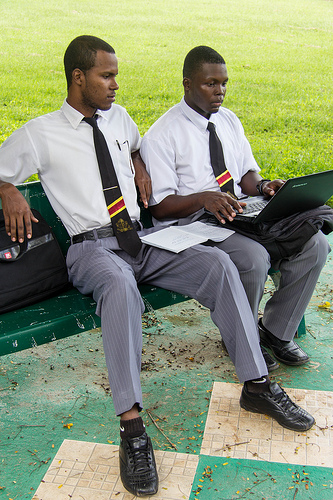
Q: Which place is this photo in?
A: It is at the field.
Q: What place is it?
A: It is a field.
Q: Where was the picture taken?
A: It was taken at the field.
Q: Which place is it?
A: It is a field.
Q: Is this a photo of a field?
A: Yes, it is showing a field.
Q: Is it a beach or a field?
A: It is a field.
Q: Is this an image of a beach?
A: No, the picture is showing a field.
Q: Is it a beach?
A: No, it is a field.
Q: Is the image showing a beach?
A: No, the picture is showing a field.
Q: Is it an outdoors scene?
A: Yes, it is outdoors.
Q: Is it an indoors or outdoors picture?
A: It is outdoors.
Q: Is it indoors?
A: No, it is outdoors.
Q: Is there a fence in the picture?
A: No, there are no fences.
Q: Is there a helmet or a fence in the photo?
A: No, there are no fences or helmets.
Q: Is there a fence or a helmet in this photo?
A: No, there are no fences or helmets.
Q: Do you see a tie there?
A: Yes, there is a tie.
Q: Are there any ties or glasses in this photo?
A: Yes, there is a tie.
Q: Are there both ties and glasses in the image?
A: No, there is a tie but no glasses.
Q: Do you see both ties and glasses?
A: No, there is a tie but no glasses.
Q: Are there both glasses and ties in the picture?
A: No, there is a tie but no glasses.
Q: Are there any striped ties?
A: Yes, there is a striped tie.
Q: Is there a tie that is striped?
A: Yes, there is a tie that is striped.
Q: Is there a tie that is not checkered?
A: Yes, there is a striped tie.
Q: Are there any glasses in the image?
A: No, there are no glasses.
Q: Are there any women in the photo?
A: No, there are no women.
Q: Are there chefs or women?
A: No, there are no women or chefs.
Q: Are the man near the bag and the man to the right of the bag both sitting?
A: Yes, both the man and the man are sitting.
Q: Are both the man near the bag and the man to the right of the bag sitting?
A: Yes, both the man and the man are sitting.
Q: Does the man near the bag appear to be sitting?
A: Yes, the man is sitting.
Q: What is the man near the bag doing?
A: The man is sitting.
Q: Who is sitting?
A: The man is sitting.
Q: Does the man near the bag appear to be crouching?
A: No, the man is sitting.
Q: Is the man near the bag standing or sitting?
A: The man is sitting.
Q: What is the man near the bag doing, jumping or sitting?
A: The man is sitting.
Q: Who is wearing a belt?
A: The man is wearing a belt.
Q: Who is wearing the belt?
A: The man is wearing a belt.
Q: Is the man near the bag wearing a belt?
A: Yes, the man is wearing a belt.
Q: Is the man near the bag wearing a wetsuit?
A: No, the man is wearing a belt.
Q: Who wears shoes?
A: The man wears shoes.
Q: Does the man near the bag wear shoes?
A: Yes, the man wears shoes.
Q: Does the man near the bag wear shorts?
A: No, the man wears shoes.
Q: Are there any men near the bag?
A: Yes, there is a man near the bag.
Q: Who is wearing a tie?
A: The man is wearing a tie.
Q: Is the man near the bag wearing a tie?
A: Yes, the man is wearing a tie.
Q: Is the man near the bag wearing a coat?
A: No, the man is wearing a tie.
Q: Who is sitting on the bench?
A: The man is sitting on the bench.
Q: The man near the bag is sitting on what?
A: The man is sitting on the bench.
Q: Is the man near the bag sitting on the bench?
A: Yes, the man is sitting on the bench.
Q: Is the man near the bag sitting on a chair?
A: No, the man is sitting on the bench.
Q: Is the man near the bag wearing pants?
A: Yes, the man is wearing pants.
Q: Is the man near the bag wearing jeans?
A: No, the man is wearing pants.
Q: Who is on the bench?
A: The man is on the bench.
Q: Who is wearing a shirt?
A: The man is wearing a shirt.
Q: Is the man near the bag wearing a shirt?
A: Yes, the man is wearing a shirt.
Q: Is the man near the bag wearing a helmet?
A: No, the man is wearing a shirt.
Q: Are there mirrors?
A: No, there are no mirrors.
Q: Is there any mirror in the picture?
A: No, there are no mirrors.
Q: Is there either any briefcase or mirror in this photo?
A: No, there are no mirrors or briefcases.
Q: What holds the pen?
A: The pocket holds the pen.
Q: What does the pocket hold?
A: The pocket holds the pen.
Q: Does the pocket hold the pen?
A: Yes, the pocket holds the pen.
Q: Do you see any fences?
A: No, there are no fences.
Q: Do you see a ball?
A: No, there are no balls.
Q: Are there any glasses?
A: No, there are no glasses.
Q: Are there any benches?
A: Yes, there is a bench.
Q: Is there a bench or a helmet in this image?
A: Yes, there is a bench.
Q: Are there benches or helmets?
A: Yes, there is a bench.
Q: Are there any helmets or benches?
A: Yes, there is a bench.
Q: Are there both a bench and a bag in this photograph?
A: Yes, there are both a bench and a bag.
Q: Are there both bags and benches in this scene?
A: Yes, there are both a bench and a bag.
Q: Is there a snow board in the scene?
A: No, there are no snowboards.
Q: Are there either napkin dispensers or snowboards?
A: No, there are no snowboards or napkin dispensers.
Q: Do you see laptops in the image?
A: Yes, there is a laptop.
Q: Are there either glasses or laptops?
A: Yes, there is a laptop.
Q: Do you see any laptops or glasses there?
A: Yes, there is a laptop.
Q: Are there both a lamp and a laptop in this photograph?
A: No, there is a laptop but no lamps.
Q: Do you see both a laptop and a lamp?
A: No, there is a laptop but no lamps.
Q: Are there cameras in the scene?
A: No, there are no cameras.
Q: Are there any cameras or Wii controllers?
A: No, there are no cameras or Wii controllers.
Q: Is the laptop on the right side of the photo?
A: Yes, the laptop is on the right of the image.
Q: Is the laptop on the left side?
A: No, the laptop is on the right of the image.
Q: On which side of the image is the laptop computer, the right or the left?
A: The laptop computer is on the right of the image.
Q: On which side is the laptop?
A: The laptop is on the right of the image.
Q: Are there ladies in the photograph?
A: No, there are no ladies.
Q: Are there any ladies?
A: No, there are no ladies.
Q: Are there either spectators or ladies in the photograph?
A: No, there are no ladies or spectators.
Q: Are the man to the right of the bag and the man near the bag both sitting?
A: Yes, both the man and the man are sitting.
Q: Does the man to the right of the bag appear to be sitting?
A: Yes, the man is sitting.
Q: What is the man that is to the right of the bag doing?
A: The man is sitting.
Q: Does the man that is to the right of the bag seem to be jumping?
A: No, the man is sitting.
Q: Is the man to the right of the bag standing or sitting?
A: The man is sitting.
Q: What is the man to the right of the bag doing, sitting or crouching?
A: The man is sitting.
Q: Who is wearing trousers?
A: The man is wearing trousers.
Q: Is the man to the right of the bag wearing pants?
A: Yes, the man is wearing pants.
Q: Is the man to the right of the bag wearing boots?
A: No, the man is wearing pants.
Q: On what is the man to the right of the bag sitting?
A: The man is sitting on the bench.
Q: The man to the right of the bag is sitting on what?
A: The man is sitting on the bench.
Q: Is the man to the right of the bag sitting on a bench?
A: Yes, the man is sitting on a bench.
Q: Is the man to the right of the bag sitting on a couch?
A: No, the man is sitting on a bench.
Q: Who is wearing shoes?
A: The man is wearing shoes.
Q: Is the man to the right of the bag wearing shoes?
A: Yes, the man is wearing shoes.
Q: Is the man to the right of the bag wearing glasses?
A: No, the man is wearing shoes.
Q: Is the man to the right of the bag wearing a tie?
A: Yes, the man is wearing a tie.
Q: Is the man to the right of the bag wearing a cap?
A: No, the man is wearing a tie.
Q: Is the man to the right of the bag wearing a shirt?
A: Yes, the man is wearing a shirt.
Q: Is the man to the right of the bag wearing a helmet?
A: No, the man is wearing a shirt.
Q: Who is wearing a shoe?
A: The man is wearing a shoe.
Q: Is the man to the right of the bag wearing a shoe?
A: Yes, the man is wearing a shoe.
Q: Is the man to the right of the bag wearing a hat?
A: No, the man is wearing a shoe.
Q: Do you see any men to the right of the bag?
A: Yes, there is a man to the right of the bag.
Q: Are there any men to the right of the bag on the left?
A: Yes, there is a man to the right of the bag.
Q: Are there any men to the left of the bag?
A: No, the man is to the right of the bag.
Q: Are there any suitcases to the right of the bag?
A: No, there is a man to the right of the bag.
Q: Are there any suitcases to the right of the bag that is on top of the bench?
A: No, there is a man to the right of the bag.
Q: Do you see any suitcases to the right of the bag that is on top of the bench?
A: No, there is a man to the right of the bag.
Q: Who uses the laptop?
A: The man uses the laptop.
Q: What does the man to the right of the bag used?
A: The man uses a laptop computer.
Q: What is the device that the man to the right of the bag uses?
A: The device is a laptop.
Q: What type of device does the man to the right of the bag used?
A: The man uses a laptop.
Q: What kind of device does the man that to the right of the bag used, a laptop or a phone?
A: The man uses a laptop.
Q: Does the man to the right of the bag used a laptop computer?
A: Yes, the man uses a laptop computer.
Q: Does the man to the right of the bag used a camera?
A: No, the man uses a laptop computer.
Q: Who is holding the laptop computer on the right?
A: The man is holding the laptop computer.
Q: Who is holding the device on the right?
A: The man is holding the laptop computer.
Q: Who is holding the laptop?
A: The man is holding the laptop computer.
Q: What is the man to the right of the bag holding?
A: The man is holding the laptop.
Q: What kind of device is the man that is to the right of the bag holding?
A: The man is holding the laptop computer.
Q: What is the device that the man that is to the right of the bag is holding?
A: The device is a laptop.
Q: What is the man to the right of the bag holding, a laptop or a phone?
A: The man is holding a laptop.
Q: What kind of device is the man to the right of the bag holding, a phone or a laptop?
A: The man is holding a laptop.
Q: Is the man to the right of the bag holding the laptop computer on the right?
A: Yes, the man is holding the laptop.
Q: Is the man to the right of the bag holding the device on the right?
A: Yes, the man is holding the laptop.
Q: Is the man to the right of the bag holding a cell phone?
A: No, the man is holding the laptop.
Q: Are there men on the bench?
A: Yes, there is a man on the bench.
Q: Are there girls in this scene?
A: No, there are no girls.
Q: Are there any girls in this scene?
A: No, there are no girls.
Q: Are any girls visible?
A: No, there are no girls.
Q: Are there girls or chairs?
A: No, there are no girls or chairs.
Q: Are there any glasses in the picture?
A: No, there are no glasses.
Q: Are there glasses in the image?
A: No, there are no glasses.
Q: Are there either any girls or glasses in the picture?
A: No, there are no glasses or girls.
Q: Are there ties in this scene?
A: Yes, there is a tie.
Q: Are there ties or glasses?
A: Yes, there is a tie.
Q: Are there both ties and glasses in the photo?
A: No, there is a tie but no glasses.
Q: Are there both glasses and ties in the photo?
A: No, there is a tie but no glasses.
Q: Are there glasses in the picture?
A: No, there are no glasses.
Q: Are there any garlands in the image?
A: No, there are no garlands.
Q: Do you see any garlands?
A: No, there are no garlands.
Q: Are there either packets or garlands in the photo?
A: No, there are no garlands or packets.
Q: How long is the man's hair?
A: The hair is short.